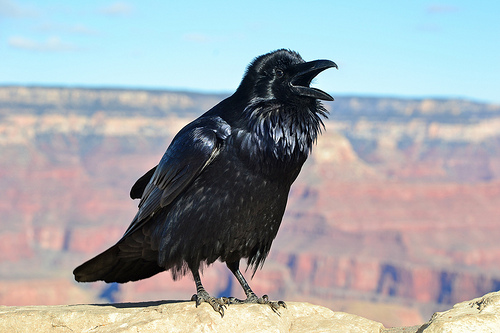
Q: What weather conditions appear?
A: It is clear.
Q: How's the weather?
A: It is clear.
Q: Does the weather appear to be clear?
A: Yes, it is clear.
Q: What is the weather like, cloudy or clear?
A: It is clear.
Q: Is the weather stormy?
A: No, it is clear.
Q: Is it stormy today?
A: No, it is clear.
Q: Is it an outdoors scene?
A: Yes, it is outdoors.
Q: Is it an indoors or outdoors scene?
A: It is outdoors.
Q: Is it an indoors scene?
A: No, it is outdoors.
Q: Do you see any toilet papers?
A: No, there are no toilet papers.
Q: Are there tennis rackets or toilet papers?
A: No, there are no toilet papers or tennis rackets.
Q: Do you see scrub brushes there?
A: No, there are no scrub brushes.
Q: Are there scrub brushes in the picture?
A: No, there are no scrub brushes.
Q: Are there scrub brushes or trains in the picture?
A: No, there are no scrub brushes or trains.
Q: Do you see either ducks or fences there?
A: No, there are no fences or ducks.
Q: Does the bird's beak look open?
A: Yes, the beak is open.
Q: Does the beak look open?
A: Yes, the beak is open.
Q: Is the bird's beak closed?
A: No, the beak is open.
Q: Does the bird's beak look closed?
A: No, the beak is open.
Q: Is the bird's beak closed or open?
A: The beak is open.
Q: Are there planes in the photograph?
A: No, there are no planes.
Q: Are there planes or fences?
A: No, there are no planes or fences.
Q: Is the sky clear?
A: Yes, the sky is clear.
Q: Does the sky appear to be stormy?
A: No, the sky is clear.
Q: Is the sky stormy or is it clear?
A: The sky is clear.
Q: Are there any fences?
A: No, there are no fences.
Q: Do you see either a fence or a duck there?
A: No, there are no fences or ducks.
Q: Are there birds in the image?
A: Yes, there is a bird.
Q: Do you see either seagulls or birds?
A: Yes, there is a bird.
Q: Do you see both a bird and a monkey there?
A: No, there is a bird but no monkeys.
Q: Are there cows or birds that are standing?
A: Yes, the bird is standing.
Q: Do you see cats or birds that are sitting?
A: Yes, the bird is sitting.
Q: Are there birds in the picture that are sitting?
A: Yes, there is a bird that is sitting.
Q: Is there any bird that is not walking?
A: Yes, there is a bird that is sitting.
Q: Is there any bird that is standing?
A: Yes, there is a bird that is standing.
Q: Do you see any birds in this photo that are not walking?
A: Yes, there is a bird that is standing .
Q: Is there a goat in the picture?
A: No, there are no goats.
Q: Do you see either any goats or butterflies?
A: No, there are no goats or butterflies.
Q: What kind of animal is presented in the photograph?
A: The animal is a bird.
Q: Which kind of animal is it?
A: The animal is a bird.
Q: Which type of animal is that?
A: That is a bird.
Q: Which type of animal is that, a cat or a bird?
A: That is a bird.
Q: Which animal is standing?
A: The animal is a bird.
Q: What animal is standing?
A: The animal is a bird.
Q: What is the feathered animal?
A: The animal is a bird.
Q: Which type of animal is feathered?
A: The animal is a bird.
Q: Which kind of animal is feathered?
A: The animal is a bird.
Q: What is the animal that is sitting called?
A: The animal is a bird.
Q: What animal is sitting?
A: The animal is a bird.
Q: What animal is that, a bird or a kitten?
A: That is a bird.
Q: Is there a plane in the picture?
A: No, there are no airplanes.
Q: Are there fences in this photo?
A: No, there are no fences.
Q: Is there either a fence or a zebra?
A: No, there are no fences or zebras.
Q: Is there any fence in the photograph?
A: No, there are no fences.